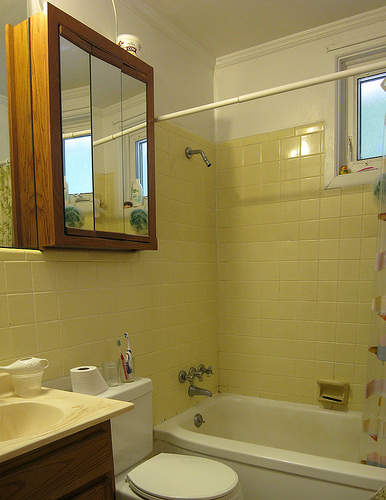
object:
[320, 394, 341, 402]
item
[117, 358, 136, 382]
glass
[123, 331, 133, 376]
toothbrush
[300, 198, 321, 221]
tile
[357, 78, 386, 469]
shower curtain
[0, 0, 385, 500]
toilet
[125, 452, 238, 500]
lid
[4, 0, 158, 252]
frame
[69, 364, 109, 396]
toilet paper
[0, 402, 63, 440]
sink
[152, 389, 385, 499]
bathtub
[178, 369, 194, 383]
faucet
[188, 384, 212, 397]
tap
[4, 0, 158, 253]
medicine cabinet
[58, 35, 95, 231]
mirror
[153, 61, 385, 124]
rod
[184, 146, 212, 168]
shower head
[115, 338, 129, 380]
toothbrush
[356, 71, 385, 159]
window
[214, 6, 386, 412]
shower wall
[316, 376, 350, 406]
soap holder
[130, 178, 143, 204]
bottle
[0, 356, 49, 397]
teapot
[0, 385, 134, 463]
counter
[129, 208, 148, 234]
shower poof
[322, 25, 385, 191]
rim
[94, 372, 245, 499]
toilet bowl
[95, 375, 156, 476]
cistern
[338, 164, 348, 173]
ducky